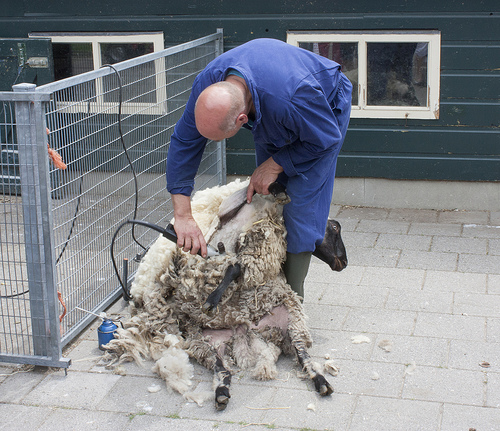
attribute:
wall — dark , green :
[1, 0, 499, 187]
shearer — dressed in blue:
[239, 56, 326, 140]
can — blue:
[95, 313, 121, 353]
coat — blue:
[168, 42, 353, 251]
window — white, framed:
[26, 32, 167, 112]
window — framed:
[283, 31, 440, 121]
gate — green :
[1, 35, 87, 194]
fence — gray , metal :
[38, 24, 226, 348]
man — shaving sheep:
[158, 35, 364, 347]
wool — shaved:
[165, 263, 207, 297]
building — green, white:
[3, 0, 499, 194]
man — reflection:
[165, 40, 355, 302]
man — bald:
[165, 29, 360, 324]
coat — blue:
[160, 32, 350, 259]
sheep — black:
[95, 152, 355, 409]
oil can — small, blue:
[78, 311, 119, 347]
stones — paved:
[383, 244, 475, 390]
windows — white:
[346, 30, 441, 120]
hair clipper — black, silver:
[164, 224, 225, 257]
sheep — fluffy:
[124, 172, 351, 415]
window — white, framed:
[283, 29, 445, 126]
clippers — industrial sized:
[165, 228, 250, 316]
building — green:
[362, 1, 483, 179]